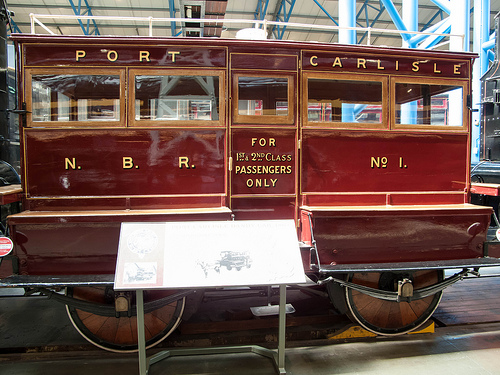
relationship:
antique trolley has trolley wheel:
[0, 29, 499, 375] [63, 280, 192, 355]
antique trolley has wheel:
[0, 29, 499, 375] [342, 268, 445, 339]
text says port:
[73, 45, 189, 69] [68, 37, 186, 69]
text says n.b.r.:
[62, 156, 218, 184] [59, 152, 191, 173]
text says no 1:
[363, 153, 411, 170] [366, 144, 407, 171]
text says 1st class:
[238, 149, 295, 163] [230, 146, 253, 164]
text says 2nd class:
[238, 149, 295, 163] [264, 148, 287, 162]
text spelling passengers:
[234, 165, 292, 186] [232, 163, 293, 174]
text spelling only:
[234, 165, 292, 186] [243, 176, 279, 187]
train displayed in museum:
[2, 30, 483, 355] [10, 23, 499, 335]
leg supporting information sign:
[133, 290, 150, 372] [111, 218, 309, 291]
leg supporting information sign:
[273, 283, 287, 373] [111, 218, 309, 291]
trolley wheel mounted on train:
[63, 280, 192, 355] [2, 30, 483, 355]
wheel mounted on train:
[342, 268, 445, 339] [2, 30, 483, 355]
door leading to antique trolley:
[227, 51, 298, 211] [0, 29, 499, 375]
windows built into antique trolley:
[16, 60, 129, 131] [0, 29, 499, 375]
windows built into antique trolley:
[127, 62, 222, 126] [0, 29, 499, 375]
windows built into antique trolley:
[232, 65, 295, 124] [0, 29, 499, 375]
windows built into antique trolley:
[300, 69, 387, 131] [0, 29, 499, 375]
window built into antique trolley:
[392, 81, 462, 124] [0, 29, 499, 375]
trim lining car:
[20, 63, 474, 133] [13, 35, 472, 215]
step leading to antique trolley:
[249, 302, 295, 317] [0, 29, 499, 375]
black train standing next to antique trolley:
[477, 10, 500, 171] [0, 29, 499, 375]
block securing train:
[322, 320, 376, 342] [2, 30, 483, 355]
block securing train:
[405, 318, 437, 336] [2, 30, 483, 355]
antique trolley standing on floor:
[0, 29, 499, 375] [430, 275, 499, 322]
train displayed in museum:
[465, 16, 499, 232] [2, 2, 484, 369]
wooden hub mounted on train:
[434, 273, 492, 316] [2, 30, 483, 355]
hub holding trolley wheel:
[71, 285, 180, 345] [63, 280, 192, 355]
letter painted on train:
[72, 48, 88, 61] [2, 30, 483, 355]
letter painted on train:
[105, 48, 117, 62] [2, 30, 483, 355]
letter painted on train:
[166, 49, 179, 63] [2, 30, 483, 355]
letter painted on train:
[138, 50, 150, 64] [2, 30, 483, 355]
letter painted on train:
[308, 54, 318, 66] [2, 30, 483, 355]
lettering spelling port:
[72, 49, 183, 64] [72, 45, 183, 64]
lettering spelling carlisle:
[309, 54, 464, 74] [306, 52, 466, 74]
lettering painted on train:
[72, 49, 183, 64] [2, 30, 483, 355]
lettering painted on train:
[309, 54, 464, 74] [2, 30, 483, 355]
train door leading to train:
[229, 52, 298, 229] [2, 30, 483, 355]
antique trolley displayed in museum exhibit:
[11, 29, 485, 265] [2, 1, 484, 372]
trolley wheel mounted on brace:
[63, 280, 192, 355] [35, 287, 195, 317]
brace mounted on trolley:
[35, 287, 195, 317] [7, 21, 496, 359]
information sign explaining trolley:
[115, 215, 309, 288] [7, 21, 496, 359]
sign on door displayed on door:
[226, 136, 302, 195] [227, 51, 298, 211]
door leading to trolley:
[227, 51, 298, 211] [7, 21, 496, 359]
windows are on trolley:
[16, 60, 129, 131] [7, 21, 496, 359]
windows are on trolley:
[127, 62, 222, 126] [7, 21, 496, 359]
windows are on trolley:
[232, 65, 295, 124] [7, 21, 496, 359]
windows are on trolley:
[300, 69, 387, 131] [7, 21, 496, 359]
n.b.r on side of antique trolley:
[55, 148, 202, 173] [0, 29, 499, 375]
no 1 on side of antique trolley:
[357, 148, 414, 172] [0, 29, 499, 375]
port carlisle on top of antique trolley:
[15, 36, 477, 76] [0, 29, 499, 375]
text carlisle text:
[309, 53, 472, 88] [73, 45, 189, 69]